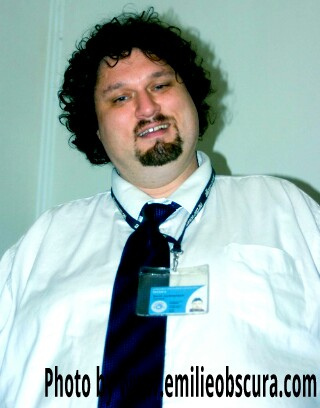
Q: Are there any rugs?
A: No, there are no rugs.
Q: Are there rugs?
A: No, there are no rugs.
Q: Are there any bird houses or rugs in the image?
A: No, there are no rugs or bird houses.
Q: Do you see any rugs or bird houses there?
A: No, there are no rugs or bird houses.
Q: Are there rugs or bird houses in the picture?
A: No, there are no rugs or bird houses.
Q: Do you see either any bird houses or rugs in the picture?
A: No, there are no rugs or bird houses.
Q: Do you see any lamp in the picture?
A: No, there are no lamps.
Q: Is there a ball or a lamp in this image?
A: No, there are no lamps or balls.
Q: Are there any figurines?
A: No, there are no figurines.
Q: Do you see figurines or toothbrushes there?
A: No, there are no figurines or toothbrushes.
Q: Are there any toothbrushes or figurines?
A: No, there are no figurines or toothbrushes.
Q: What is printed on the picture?
A: The letter is printed on the picture.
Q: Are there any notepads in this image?
A: No, there are no notepads.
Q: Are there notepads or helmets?
A: No, there are no notepads or helmets.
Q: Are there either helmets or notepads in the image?
A: No, there are no notepads or helmets.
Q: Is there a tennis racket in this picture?
A: No, there are no rackets.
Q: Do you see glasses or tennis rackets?
A: No, there are no tennis rackets or glasses.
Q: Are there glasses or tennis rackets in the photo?
A: No, there are no tennis rackets or glasses.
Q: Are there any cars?
A: No, there are no cars.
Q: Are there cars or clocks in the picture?
A: No, there are no cars or clocks.